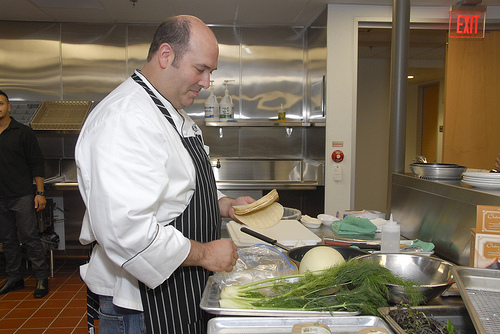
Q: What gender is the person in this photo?
A: Male.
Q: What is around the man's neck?
A: An apron.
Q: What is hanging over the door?
A: An exit sign.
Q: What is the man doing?
A: Preparing a meal.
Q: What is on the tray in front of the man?
A: Fresh herbs.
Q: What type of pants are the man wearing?
A: Blue jeans.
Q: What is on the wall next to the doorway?
A: Fire alarm.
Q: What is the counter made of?
A: Steel.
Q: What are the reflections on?
A: Chrome wall.